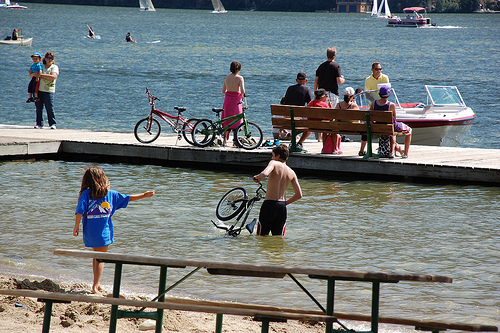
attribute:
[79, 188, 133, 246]
shirt — blue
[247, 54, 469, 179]
bench — wooden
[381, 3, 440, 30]
boat — white, red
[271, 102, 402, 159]
bench — full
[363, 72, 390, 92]
shirt — yellow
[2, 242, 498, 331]
picnic table — wood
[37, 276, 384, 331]
legs — metal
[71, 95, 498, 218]
dock — long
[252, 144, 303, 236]
boy — holding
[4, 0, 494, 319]
water — blue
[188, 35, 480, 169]
speedboat — Small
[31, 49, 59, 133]
woman — holding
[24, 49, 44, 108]
boy — little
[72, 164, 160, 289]
girl — little, standing